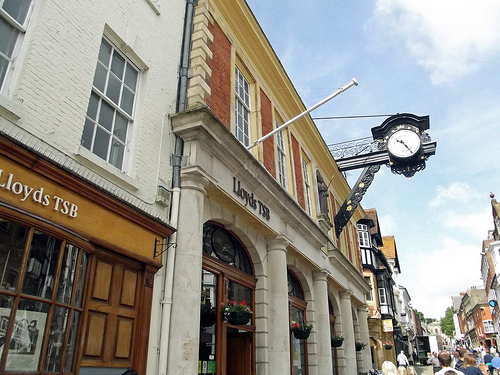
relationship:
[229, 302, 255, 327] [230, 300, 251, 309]
basket with flowers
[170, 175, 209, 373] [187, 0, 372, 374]
pillar on building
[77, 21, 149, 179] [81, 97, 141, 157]
window with panes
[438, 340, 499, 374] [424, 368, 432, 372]
people in street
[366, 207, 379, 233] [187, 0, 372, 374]
roof of building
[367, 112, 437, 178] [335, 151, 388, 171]
clock on beam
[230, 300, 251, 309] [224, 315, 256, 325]
flowers in pot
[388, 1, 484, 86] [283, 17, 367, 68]
clouds in sky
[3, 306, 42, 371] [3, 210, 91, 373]
advertisement in window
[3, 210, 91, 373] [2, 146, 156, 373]
window of store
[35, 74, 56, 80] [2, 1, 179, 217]
bricks on wall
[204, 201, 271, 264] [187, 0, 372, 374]
archway on building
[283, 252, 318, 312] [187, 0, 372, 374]
archway on building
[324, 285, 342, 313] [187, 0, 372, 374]
archway on building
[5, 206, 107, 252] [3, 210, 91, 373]
frame of window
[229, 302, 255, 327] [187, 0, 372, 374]
plant hanger on building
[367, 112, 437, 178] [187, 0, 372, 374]
clock on building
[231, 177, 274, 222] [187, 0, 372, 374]
lloyds tsb on building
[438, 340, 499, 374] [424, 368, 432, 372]
people on street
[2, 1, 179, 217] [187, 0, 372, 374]
wall of building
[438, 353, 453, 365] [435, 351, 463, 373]
head of person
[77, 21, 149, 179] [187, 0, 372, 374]
window on building